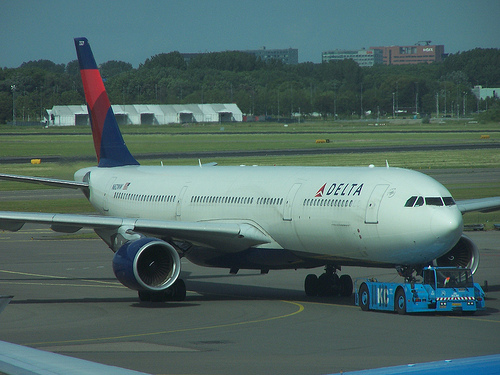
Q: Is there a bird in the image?
A: No, there are no birds.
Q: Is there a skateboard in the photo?
A: No, there are no skateboards.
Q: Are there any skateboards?
A: No, there are no skateboards.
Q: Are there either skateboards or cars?
A: No, there are no skateboards or cars.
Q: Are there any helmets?
A: No, there are no helmets.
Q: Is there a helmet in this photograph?
A: No, there are no helmets.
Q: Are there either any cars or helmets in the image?
A: No, there are no helmets or cars.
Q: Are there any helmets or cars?
A: No, there are no helmets or cars.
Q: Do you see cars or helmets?
A: No, there are no helmets or cars.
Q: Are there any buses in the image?
A: No, there are no buses.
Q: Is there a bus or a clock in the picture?
A: No, there are no buses or clocks.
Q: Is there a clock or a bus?
A: No, there are no buses or clocks.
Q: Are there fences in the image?
A: No, there are no fences.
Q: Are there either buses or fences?
A: No, there are no fences or buses.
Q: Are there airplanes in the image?
A: Yes, there is an airplane.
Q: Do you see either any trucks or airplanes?
A: Yes, there is an airplane.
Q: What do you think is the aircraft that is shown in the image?
A: The aircraft is an airplane.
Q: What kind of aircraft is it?
A: The aircraft is an airplane.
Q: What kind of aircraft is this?
A: This is an airplane.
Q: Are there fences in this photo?
A: No, there are no fences.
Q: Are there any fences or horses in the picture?
A: No, there are no fences or horses.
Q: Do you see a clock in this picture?
A: No, there are no clocks.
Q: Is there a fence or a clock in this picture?
A: No, there are no clocks or fences.